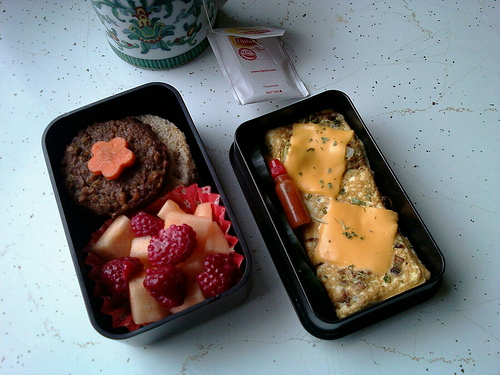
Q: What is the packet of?
A: Teabag.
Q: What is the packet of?
A: Teabag.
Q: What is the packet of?
A: Teabag.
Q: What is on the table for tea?
A: A packet of teabag.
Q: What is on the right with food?
A: Black pan.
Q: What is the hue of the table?
A: White.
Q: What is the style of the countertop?
A: Marble.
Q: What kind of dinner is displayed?
A: Tv dinner.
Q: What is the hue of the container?
A: Black.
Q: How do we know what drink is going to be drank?
A: Tea bag.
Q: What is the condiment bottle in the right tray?
A: Ketchup.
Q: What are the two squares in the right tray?
A: Cheese.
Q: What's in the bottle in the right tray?
A: Ketchup.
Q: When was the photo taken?
A: Daytime.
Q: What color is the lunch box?
A: Black.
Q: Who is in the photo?
A: Nobody.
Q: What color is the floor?
A: White.